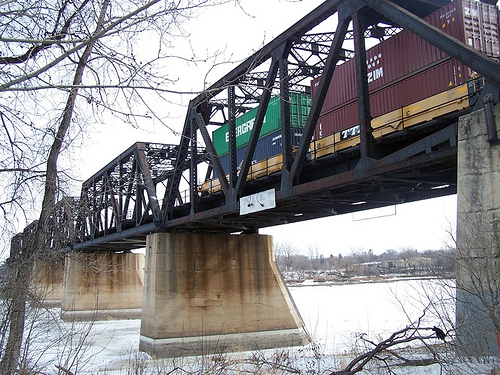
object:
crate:
[303, 0, 499, 165]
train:
[202, 5, 498, 188]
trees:
[3, 39, 93, 370]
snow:
[308, 285, 420, 342]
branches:
[14, 44, 144, 139]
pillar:
[452, 98, 498, 358]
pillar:
[141, 227, 311, 360]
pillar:
[60, 250, 148, 324]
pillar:
[26, 261, 63, 308]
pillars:
[458, 135, 496, 270]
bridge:
[102, 72, 264, 236]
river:
[4, 268, 498, 373]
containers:
[311, 0, 499, 137]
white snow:
[9, 272, 465, 370]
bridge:
[6, 3, 496, 365]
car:
[310, 21, 462, 142]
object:
[431, 322, 447, 340]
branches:
[329, 284, 489, 374]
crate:
[211, 124, 315, 191]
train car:
[308, 6, 497, 126]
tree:
[1, 2, 221, 372]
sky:
[1, 1, 284, 143]